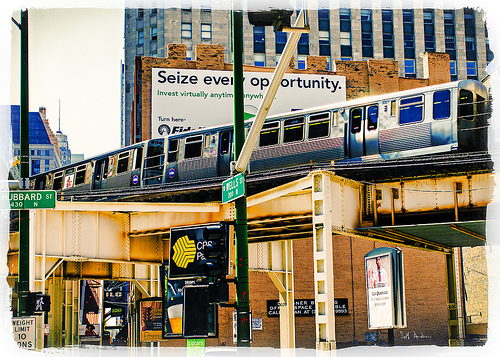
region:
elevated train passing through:
[43, 66, 478, 216]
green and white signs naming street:
[10, 170, 265, 205]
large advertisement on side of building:
[120, 50, 440, 135]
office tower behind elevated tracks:
[245, 10, 485, 75]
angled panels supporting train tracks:
[30, 175, 475, 235]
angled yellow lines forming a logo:
[160, 225, 231, 270]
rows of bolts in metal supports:
[65, 210, 96, 260]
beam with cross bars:
[301, 170, 333, 345]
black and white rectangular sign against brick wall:
[250, 290, 360, 325]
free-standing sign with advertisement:
[353, 240, 414, 331]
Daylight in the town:
[31, 13, 118, 107]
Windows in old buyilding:
[132, 9, 232, 39]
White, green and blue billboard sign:
[138, 53, 353, 108]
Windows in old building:
[356, 12, 485, 52]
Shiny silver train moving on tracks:
[296, 87, 491, 164]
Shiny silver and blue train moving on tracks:
[67, 131, 227, 196]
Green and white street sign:
[14, 155, 71, 231]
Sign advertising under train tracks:
[321, 190, 477, 342]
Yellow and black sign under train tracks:
[137, 213, 240, 299]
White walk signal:
[13, 262, 66, 337]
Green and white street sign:
[213, 177, 278, 212]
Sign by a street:
[353, 240, 439, 339]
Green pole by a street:
[189, 108, 331, 341]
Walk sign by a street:
[15, 285, 75, 331]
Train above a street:
[106, 96, 355, 171]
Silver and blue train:
[127, 128, 389, 191]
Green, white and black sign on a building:
[141, 62, 389, 156]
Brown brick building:
[126, 32, 491, 217]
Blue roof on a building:
[11, 101, 78, 176]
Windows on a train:
[245, 117, 382, 149]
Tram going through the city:
[152, 53, 358, 171]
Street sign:
[196, 156, 267, 234]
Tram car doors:
[344, 105, 374, 147]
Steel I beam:
[293, 176, 340, 356]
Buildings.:
[50, 78, 305, 193]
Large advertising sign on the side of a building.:
[154, 56, 379, 154]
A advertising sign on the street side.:
[364, 240, 445, 351]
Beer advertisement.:
[155, 281, 195, 336]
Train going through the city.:
[191, 105, 420, 184]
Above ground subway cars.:
[43, 133, 438, 288]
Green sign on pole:
[8, 186, 63, 214]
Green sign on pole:
[212, 167, 248, 208]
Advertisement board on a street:
[355, 237, 415, 342]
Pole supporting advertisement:
[381, 325, 401, 345]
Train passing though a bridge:
[0, 69, 493, 216]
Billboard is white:
[143, 60, 356, 147]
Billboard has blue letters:
[147, 63, 354, 141]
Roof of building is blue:
[7, 106, 54, 151]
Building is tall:
[113, 9, 491, 134]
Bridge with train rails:
[14, 154, 490, 209]